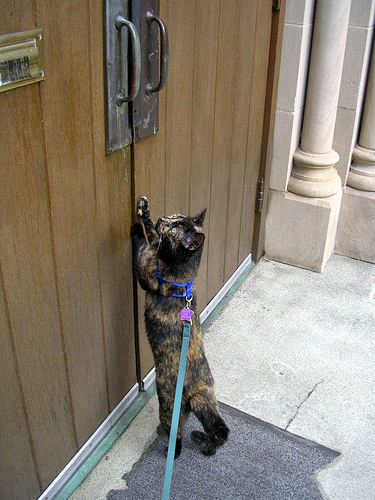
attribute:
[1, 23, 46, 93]
slot — gold, brass, golden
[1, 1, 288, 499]
door — brown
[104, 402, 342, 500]
mat — gray, torn, worn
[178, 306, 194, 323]
tag — indetification, star, purple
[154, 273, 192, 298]
harness — blue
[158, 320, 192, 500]
leash — outstretched, blue, green, canvas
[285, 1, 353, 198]
pillar — concrete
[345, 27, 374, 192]
cloumn — smooth, concrete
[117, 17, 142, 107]
handle — metal, brass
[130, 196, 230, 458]
cat — calico, scratching, brown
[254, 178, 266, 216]
hinge — bronze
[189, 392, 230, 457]
tail — black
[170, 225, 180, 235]
eye — beady